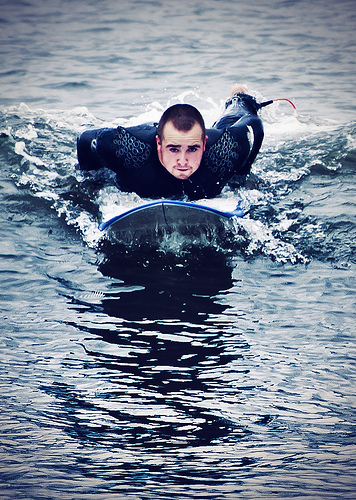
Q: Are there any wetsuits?
A: Yes, there is a wetsuit.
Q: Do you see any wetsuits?
A: Yes, there is a wetsuit.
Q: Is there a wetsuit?
A: Yes, there is a wetsuit.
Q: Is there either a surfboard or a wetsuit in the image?
A: Yes, there is a wetsuit.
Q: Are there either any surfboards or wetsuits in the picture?
A: Yes, there is a wetsuit.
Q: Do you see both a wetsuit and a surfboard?
A: Yes, there are both a wetsuit and a surfboard.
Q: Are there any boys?
A: No, there are no boys.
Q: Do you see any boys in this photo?
A: No, there are no boys.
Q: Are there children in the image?
A: No, there are no children.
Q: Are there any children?
A: No, there are no children.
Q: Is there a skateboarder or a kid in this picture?
A: No, there are no children or skateboarders.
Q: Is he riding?
A: Yes, the man is riding.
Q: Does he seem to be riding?
A: Yes, the man is riding.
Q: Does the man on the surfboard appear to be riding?
A: Yes, the man is riding.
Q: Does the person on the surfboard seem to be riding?
A: Yes, the man is riding.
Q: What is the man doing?
A: The man is riding.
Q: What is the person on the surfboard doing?
A: The man is riding.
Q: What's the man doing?
A: The man is riding.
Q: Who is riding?
A: The man is riding.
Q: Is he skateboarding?
A: No, the man is riding.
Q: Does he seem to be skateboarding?
A: No, the man is riding.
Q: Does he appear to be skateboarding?
A: No, the man is riding.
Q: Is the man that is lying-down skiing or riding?
A: The man is riding.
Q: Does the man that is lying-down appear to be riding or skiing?
A: The man is riding.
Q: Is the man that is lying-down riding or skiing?
A: The man is riding.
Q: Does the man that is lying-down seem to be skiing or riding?
A: The man is riding.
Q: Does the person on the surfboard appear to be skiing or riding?
A: The man is riding.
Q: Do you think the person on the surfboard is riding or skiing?
A: The man is riding.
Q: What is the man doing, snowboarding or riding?
A: The man is riding.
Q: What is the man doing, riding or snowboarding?
A: The man is riding.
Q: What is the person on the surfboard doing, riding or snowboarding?
A: The man is riding.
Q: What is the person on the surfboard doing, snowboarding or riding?
A: The man is riding.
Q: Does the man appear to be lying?
A: Yes, the man is lying.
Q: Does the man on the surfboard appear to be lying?
A: Yes, the man is lying.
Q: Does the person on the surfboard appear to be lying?
A: Yes, the man is lying.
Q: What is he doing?
A: The man is lying.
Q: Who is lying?
A: The man is lying.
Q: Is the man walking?
A: No, the man is lying.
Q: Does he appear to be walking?
A: No, the man is lying.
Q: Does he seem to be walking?
A: No, the man is lying.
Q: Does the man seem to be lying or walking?
A: The man is lying.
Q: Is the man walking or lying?
A: The man is lying.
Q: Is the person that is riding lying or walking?
A: The man is lying.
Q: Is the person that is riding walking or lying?
A: The man is lying.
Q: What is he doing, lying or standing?
A: The man is lying.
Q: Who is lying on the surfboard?
A: The man is lying on the surfboard.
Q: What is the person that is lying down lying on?
A: The man is lying on the surfboard.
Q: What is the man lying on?
A: The man is lying on the surfboard.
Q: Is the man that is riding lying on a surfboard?
A: Yes, the man is lying on a surfboard.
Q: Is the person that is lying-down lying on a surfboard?
A: Yes, the man is lying on a surfboard.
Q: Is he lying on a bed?
A: No, the man is lying on a surfboard.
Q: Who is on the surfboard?
A: The man is on the surfboard.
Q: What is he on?
A: The man is on the surfboard.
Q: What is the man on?
A: The man is on the surfboard.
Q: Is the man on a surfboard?
A: Yes, the man is on a surfboard.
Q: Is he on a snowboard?
A: No, the man is on a surfboard.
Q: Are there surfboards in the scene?
A: Yes, there is a surfboard.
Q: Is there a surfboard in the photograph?
A: Yes, there is a surfboard.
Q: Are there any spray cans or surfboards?
A: Yes, there is a surfboard.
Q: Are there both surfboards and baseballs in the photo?
A: No, there is a surfboard but no baseballs.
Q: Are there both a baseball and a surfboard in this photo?
A: No, there is a surfboard but no baseballs.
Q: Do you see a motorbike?
A: No, there are no motorcycles.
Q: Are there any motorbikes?
A: No, there are no motorbikes.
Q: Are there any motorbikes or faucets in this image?
A: No, there are no motorbikes or faucets.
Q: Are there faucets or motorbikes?
A: No, there are no motorbikes or faucets.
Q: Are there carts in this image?
A: No, there are no carts.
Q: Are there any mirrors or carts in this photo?
A: No, there are no carts or mirrors.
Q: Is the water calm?
A: Yes, the water is calm.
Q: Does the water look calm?
A: Yes, the water is calm.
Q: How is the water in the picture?
A: The water is calm.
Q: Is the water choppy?
A: No, the water is calm.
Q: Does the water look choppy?
A: No, the water is calm.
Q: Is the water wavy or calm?
A: The water is calm.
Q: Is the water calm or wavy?
A: The water is calm.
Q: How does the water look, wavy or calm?
A: The water is calm.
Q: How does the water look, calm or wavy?
A: The water is calm.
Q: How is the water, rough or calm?
A: The water is calm.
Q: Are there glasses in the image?
A: No, there are no glasses.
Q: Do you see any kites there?
A: No, there are no kites.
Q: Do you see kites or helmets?
A: No, there are no kites or helmets.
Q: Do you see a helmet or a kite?
A: No, there are no kites or helmets.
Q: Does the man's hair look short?
A: Yes, the hair is short.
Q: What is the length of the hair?
A: The hair is short.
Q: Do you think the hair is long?
A: No, the hair is short.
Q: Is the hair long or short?
A: The hair is short.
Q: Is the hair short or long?
A: The hair is short.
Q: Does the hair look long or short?
A: The hair is short.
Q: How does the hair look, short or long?
A: The hair is short.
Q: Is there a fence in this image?
A: No, there are no fences.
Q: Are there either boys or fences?
A: No, there are no fences or boys.